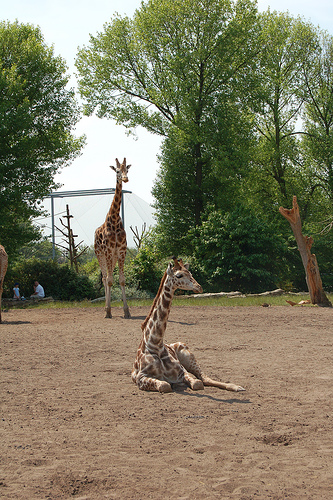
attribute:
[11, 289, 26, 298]
shirt — light blue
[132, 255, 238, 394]
giraffe — sitting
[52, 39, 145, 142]
clouds — thin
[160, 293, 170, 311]
spots — brown and white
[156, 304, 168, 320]
spots — brown and white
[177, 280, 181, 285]
spots — brown and white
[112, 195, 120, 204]
spots — brown and white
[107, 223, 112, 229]
spots — brown and white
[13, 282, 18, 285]
hat — blue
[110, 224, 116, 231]
spot — brown, orange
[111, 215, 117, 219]
spot — brown, orange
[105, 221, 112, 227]
spot — brown, orange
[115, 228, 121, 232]
spot — brown, orange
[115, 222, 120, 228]
spot — brown, orange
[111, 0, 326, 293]
leafy trees — green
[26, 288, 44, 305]
pants — beige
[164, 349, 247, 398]
legs — white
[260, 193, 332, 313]
trunk — large, brown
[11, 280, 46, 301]
people — sitting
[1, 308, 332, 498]
ground — dirt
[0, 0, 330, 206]
sky — white, blue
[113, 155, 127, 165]
ossicles — large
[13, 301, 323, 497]
field — big, dirt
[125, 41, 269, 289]
trees — leafy